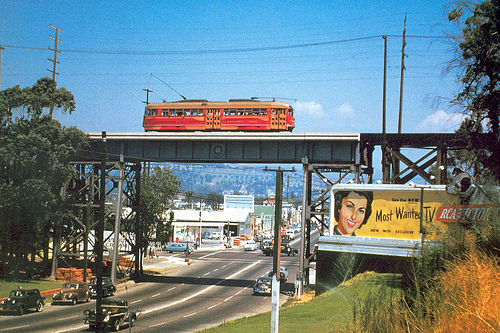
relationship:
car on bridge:
[139, 96, 295, 133] [2, 131, 496, 297]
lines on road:
[0, 249, 282, 331] [145, 289, 262, 312]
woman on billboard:
[332, 190, 372, 237] [328, 182, 460, 241]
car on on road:
[164, 242, 192, 253] [184, 254, 327, 329]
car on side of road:
[1, 287, 46, 316] [24, 316, 88, 327]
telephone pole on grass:
[273, 172, 280, 278] [281, 304, 363, 331]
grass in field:
[437, 258, 497, 326] [206, 240, 490, 325]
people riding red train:
[223, 109, 267, 115] [140, 99, 297, 134]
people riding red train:
[146, 108, 206, 118] [140, 99, 297, 134]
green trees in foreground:
[13, 105, 105, 243] [204, 271, 398, 332]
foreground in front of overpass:
[204, 271, 398, 332] [97, 100, 414, 183]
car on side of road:
[1, 287, 44, 319] [1, 231, 320, 331]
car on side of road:
[49, 279, 96, 304] [1, 231, 320, 331]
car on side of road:
[77, 272, 116, 304] [1, 231, 320, 331]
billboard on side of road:
[289, 180, 496, 253] [133, 210, 311, 321]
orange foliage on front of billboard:
[419, 244, 497, 330] [330, 189, 465, 239]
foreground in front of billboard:
[204, 271, 398, 332] [321, 179, 499, 266]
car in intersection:
[167, 237, 201, 267] [176, 242, 315, 279]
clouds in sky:
[294, 94, 471, 131] [294, 23, 444, 106]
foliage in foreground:
[342, 223, 499, 331] [295, 278, 383, 331]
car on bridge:
[146, 87, 286, 126] [172, 140, 299, 153]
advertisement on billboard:
[342, 193, 460, 229] [328, 181, 499, 243]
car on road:
[1, 287, 46, 316] [144, 285, 204, 315]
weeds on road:
[364, 234, 499, 322] [204, 270, 250, 308]